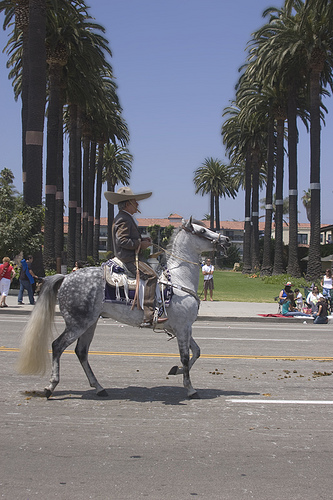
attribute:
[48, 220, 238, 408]
horse — gray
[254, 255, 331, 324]
people — sitting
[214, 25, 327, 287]
trees — lined-up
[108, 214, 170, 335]
costume — brown